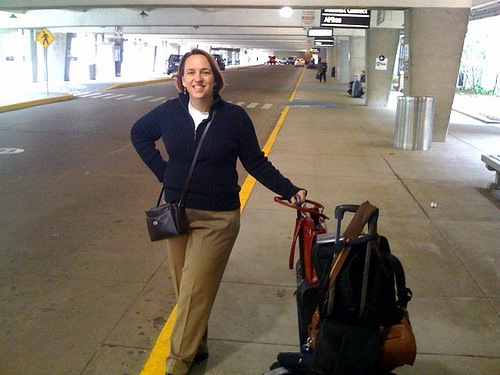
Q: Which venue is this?
A: This is an airport.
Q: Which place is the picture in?
A: It is at the airport.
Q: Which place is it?
A: It is an airport.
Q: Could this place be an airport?
A: Yes, it is an airport.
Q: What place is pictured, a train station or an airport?
A: It is an airport.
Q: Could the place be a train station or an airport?
A: It is an airport.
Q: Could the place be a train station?
A: No, it is an airport.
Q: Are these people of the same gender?
A: No, they are both male and female.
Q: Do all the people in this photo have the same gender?
A: No, they are both male and female.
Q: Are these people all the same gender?
A: No, they are both male and female.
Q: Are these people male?
A: No, they are both male and female.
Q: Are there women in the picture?
A: Yes, there is a woman.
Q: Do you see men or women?
A: Yes, there is a woman.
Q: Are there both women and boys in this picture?
A: No, there is a woman but no boys.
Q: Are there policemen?
A: No, there are no policemen.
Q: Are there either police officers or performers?
A: No, there are no police officers or performers.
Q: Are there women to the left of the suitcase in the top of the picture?
A: Yes, there is a woman to the left of the suitcase.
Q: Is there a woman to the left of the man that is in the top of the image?
A: Yes, there is a woman to the left of the man.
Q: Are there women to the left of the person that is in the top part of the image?
A: Yes, there is a woman to the left of the man.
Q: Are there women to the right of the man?
A: No, the woman is to the left of the man.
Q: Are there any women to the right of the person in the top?
A: No, the woman is to the left of the man.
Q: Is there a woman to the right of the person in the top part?
A: No, the woman is to the left of the man.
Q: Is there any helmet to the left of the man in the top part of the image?
A: No, there is a woman to the left of the man.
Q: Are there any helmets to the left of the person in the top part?
A: No, there is a woman to the left of the man.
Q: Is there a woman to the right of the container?
A: No, the woman is to the left of the container.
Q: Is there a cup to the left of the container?
A: No, there is a woman to the left of the container.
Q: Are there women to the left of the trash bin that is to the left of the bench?
A: Yes, there is a woman to the left of the garbage can.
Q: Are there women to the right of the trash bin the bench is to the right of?
A: No, the woman is to the left of the garbage bin.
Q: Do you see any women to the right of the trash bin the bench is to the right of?
A: No, the woman is to the left of the garbage bin.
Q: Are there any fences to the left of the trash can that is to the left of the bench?
A: No, there is a woman to the left of the trash bin.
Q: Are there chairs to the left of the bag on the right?
A: No, there is a woman to the left of the bag.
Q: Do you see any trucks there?
A: No, there are no trucks.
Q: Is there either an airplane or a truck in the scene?
A: No, there are no trucks or airplanes.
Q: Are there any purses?
A: Yes, there is a purse.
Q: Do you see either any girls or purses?
A: Yes, there is a purse.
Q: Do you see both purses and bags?
A: Yes, there are both a purse and a bag.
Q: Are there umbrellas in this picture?
A: No, there are no umbrellas.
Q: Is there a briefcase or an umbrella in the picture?
A: No, there are no umbrellas or briefcases.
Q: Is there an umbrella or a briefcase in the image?
A: No, there are no umbrellas or briefcases.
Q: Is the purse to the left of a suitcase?
A: Yes, the purse is to the left of a suitcase.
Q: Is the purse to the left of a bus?
A: No, the purse is to the left of a suitcase.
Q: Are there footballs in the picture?
A: No, there are no footballs.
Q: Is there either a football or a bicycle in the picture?
A: No, there are no footballs or bicycles.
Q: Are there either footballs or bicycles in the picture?
A: No, there are no footballs or bicycles.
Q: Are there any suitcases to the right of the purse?
A: Yes, there is a suitcase to the right of the purse.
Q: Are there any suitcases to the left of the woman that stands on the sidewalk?
A: No, the suitcase is to the right of the woman.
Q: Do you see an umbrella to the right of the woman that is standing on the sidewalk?
A: No, there is a suitcase to the right of the woman.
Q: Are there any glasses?
A: No, there are no glasses.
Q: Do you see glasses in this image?
A: No, there are no glasses.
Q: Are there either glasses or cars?
A: No, there are no glasses or cars.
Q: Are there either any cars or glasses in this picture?
A: No, there are no glasses or cars.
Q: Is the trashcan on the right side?
A: Yes, the trashcan is on the right of the image.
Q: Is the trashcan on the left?
A: No, the trashcan is on the right of the image.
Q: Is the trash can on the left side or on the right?
A: The trash can is on the right of the image.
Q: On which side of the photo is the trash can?
A: The trash can is on the right of the image.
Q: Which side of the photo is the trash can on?
A: The trash can is on the right of the image.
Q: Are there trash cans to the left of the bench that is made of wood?
A: Yes, there is a trash can to the left of the bench.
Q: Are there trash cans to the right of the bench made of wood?
A: No, the trash can is to the left of the bench.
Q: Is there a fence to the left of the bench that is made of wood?
A: No, there is a trash can to the left of the bench.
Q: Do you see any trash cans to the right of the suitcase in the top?
A: Yes, there is a trash can to the right of the suitcase.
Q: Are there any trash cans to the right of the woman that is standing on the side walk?
A: Yes, there is a trash can to the right of the woman.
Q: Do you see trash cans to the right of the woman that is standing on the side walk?
A: Yes, there is a trash can to the right of the woman.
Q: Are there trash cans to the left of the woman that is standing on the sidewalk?
A: No, the trash can is to the right of the woman.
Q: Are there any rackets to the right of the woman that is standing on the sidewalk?
A: No, there is a trash can to the right of the woman.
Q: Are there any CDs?
A: No, there are no cds.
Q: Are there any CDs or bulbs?
A: No, there are no CDs or bulbs.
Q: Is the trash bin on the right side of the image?
A: Yes, the trash bin is on the right of the image.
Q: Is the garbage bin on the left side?
A: No, the garbage bin is on the right of the image.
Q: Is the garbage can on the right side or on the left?
A: The garbage can is on the right of the image.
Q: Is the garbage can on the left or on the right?
A: The garbage can is on the right of the image.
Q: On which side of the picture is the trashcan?
A: The trashcan is on the right of the image.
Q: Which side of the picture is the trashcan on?
A: The trashcan is on the right of the image.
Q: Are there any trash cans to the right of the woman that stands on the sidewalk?
A: Yes, there is a trash can to the right of the woman.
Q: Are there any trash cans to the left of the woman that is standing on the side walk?
A: No, the trash can is to the right of the woman.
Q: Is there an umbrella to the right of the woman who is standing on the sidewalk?
A: No, there is a trash can to the right of the woman.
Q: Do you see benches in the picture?
A: Yes, there is a bench.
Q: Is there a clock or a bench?
A: Yes, there is a bench.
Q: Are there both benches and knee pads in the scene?
A: No, there is a bench but no knee pads.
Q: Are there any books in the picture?
A: No, there are no books.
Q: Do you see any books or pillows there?
A: No, there are no books or pillows.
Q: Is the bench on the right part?
A: Yes, the bench is on the right of the image.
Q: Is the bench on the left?
A: No, the bench is on the right of the image.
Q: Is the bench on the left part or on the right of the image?
A: The bench is on the right of the image.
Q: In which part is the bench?
A: The bench is on the right of the image.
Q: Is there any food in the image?
A: No, there is no food.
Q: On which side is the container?
A: The container is on the right of the image.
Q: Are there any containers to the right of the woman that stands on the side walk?
A: Yes, there is a container to the right of the woman.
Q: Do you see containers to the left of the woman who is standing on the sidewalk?
A: No, the container is to the right of the woman.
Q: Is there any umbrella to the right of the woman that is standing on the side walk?
A: No, there is a container to the right of the woman.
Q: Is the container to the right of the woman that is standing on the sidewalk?
A: Yes, the container is to the right of the woman.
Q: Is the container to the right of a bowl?
A: No, the container is to the right of the woman.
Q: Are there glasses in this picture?
A: No, there are no glasses.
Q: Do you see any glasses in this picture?
A: No, there are no glasses.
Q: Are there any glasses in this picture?
A: No, there are no glasses.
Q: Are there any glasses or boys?
A: No, there are no glasses or boys.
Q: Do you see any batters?
A: No, there are no batters.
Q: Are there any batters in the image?
A: No, there are no batters.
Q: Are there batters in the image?
A: No, there are no batters.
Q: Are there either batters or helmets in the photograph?
A: No, there are no batters or helmets.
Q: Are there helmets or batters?
A: No, there are no batters or helmets.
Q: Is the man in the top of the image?
A: Yes, the man is in the top of the image.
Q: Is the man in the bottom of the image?
A: No, the man is in the top of the image.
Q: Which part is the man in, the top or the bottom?
A: The man is in the top of the image.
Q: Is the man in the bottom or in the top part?
A: The man is in the top of the image.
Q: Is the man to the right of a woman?
A: Yes, the man is to the right of a woman.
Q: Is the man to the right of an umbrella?
A: No, the man is to the right of a woman.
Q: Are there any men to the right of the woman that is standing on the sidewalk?
A: Yes, there is a man to the right of the woman.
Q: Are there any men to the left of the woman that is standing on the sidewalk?
A: No, the man is to the right of the woman.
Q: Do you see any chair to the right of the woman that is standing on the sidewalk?
A: No, there is a man to the right of the woman.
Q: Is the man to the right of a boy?
A: No, the man is to the right of a woman.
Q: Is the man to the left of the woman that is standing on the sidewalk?
A: No, the man is to the right of the woman.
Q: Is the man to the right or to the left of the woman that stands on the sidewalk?
A: The man is to the right of the woman.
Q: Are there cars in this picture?
A: No, there are no cars.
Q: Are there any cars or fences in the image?
A: No, there are no cars or fences.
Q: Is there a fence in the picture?
A: No, there are no fences.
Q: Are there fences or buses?
A: No, there are no fences or buses.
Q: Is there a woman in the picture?
A: Yes, there is a woman.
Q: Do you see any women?
A: Yes, there is a woman.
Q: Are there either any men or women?
A: Yes, there is a woman.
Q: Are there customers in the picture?
A: No, there are no customers.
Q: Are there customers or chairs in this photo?
A: No, there are no customers or chairs.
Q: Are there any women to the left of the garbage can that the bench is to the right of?
A: Yes, there is a woman to the left of the garbage bin.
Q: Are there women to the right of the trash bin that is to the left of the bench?
A: No, the woman is to the left of the trash can.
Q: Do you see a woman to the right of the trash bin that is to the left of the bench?
A: No, the woman is to the left of the trash can.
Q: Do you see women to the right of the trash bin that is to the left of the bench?
A: No, the woman is to the left of the trash can.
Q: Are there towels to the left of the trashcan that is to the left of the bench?
A: No, there is a woman to the left of the trash can.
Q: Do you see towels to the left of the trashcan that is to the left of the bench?
A: No, there is a woman to the left of the trash can.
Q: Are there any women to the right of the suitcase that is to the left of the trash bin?
A: No, the woman is to the left of the suitcase.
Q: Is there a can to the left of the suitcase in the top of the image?
A: No, there is a woman to the left of the suitcase.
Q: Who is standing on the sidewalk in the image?
A: The woman is standing on the sidewalk.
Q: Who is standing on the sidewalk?
A: The woman is standing on the sidewalk.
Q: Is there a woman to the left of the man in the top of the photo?
A: Yes, there is a woman to the left of the man.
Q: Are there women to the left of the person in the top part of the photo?
A: Yes, there is a woman to the left of the man.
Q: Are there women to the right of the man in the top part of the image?
A: No, the woman is to the left of the man.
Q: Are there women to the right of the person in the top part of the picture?
A: No, the woman is to the left of the man.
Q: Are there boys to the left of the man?
A: No, there is a woman to the left of the man.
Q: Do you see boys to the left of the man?
A: No, there is a woman to the left of the man.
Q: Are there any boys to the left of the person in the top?
A: No, there is a woman to the left of the man.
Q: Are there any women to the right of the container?
A: No, the woman is to the left of the container.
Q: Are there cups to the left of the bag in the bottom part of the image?
A: No, there is a woman to the left of the bag.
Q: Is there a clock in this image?
A: No, there are no clocks.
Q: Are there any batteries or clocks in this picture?
A: No, there are no clocks or batteries.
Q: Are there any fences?
A: No, there are no fences.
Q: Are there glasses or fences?
A: No, there are no fences or glasses.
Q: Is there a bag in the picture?
A: Yes, there is a bag.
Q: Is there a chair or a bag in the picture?
A: Yes, there is a bag.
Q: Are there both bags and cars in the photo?
A: No, there is a bag but no cars.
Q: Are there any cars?
A: No, there are no cars.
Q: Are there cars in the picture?
A: No, there are no cars.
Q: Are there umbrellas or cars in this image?
A: No, there are no cars or umbrellas.